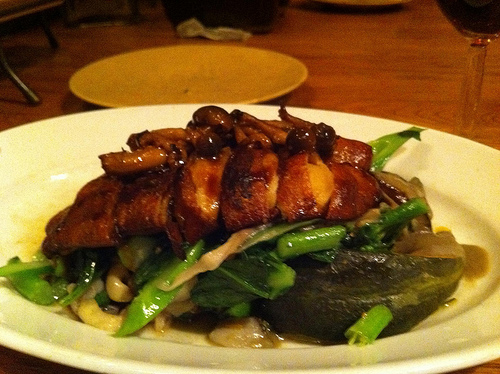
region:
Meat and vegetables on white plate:
[1, 102, 488, 372]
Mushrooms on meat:
[99, 105, 341, 177]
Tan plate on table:
[65, 40, 310, 109]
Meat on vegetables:
[0, 139, 465, 345]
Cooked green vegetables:
[0, 200, 469, 344]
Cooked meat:
[39, 143, 384, 255]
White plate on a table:
[1, 100, 499, 369]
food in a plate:
[329, 121, 473, 324]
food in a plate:
[168, 156, 255, 300]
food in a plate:
[41, 200, 170, 354]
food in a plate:
[108, 116, 245, 299]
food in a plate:
[176, 90, 290, 245]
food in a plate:
[266, 166, 407, 356]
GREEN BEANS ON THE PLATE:
[350, 305, 389, 339]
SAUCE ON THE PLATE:
[225, 325, 273, 347]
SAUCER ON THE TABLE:
[74, 39, 304, 106]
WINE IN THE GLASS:
[448, 0, 499, 43]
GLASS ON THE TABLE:
[461, 40, 497, 133]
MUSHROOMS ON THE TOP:
[128, 145, 174, 157]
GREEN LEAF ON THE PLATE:
[18, 262, 52, 297]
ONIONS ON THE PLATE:
[91, 305, 108, 325]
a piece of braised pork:
[41, 132, 381, 249]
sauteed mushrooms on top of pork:
[99, 106, 347, 171]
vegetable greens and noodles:
[1, 122, 464, 347]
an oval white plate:
[0, 104, 499, 371]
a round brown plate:
[68, 43, 308, 103]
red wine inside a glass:
[440, 2, 498, 39]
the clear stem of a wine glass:
[462, 37, 482, 137]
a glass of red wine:
[434, 0, 497, 139]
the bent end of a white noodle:
[106, 264, 133, 298]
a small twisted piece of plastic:
[179, 17, 249, 39]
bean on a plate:
[350, 305, 386, 346]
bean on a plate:
[305, 226, 350, 247]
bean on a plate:
[126, 293, 169, 345]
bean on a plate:
[31, 271, 62, 303]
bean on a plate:
[380, 118, 421, 153]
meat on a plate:
[35, 118, 376, 246]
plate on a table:
[235, 35, 302, 95]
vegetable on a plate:
[416, 245, 456, 290]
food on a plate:
[13, 115, 468, 323]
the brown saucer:
[64, 35, 310, 103]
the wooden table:
[1, 2, 498, 372]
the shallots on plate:
[71, 228, 293, 348]